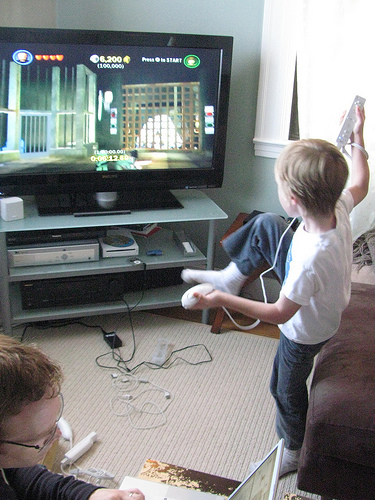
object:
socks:
[180, 261, 246, 306]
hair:
[274, 139, 348, 222]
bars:
[121, 80, 201, 89]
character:
[10, 48, 33, 65]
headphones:
[108, 365, 177, 428]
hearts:
[33, 54, 43, 62]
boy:
[0, 335, 145, 498]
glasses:
[0, 389, 66, 457]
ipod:
[126, 255, 144, 267]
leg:
[232, 212, 288, 289]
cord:
[110, 258, 150, 363]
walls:
[226, 6, 374, 305]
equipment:
[2, 226, 101, 268]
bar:
[40, 204, 184, 218]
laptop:
[117, 435, 289, 499]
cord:
[35, 320, 105, 334]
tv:
[0, 27, 239, 215]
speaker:
[94, 192, 118, 202]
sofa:
[295, 272, 374, 500]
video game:
[98, 230, 138, 259]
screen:
[225, 448, 279, 500]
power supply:
[100, 330, 120, 350]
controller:
[62, 431, 97, 467]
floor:
[3, 296, 304, 500]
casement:
[251, 1, 374, 151]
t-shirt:
[279, 195, 360, 345]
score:
[97, 52, 131, 70]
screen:
[0, 44, 219, 177]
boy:
[175, 91, 372, 487]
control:
[332, 95, 365, 153]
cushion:
[300, 277, 375, 473]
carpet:
[19, 301, 305, 496]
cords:
[94, 344, 215, 375]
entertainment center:
[6, 207, 207, 313]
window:
[252, 2, 373, 164]